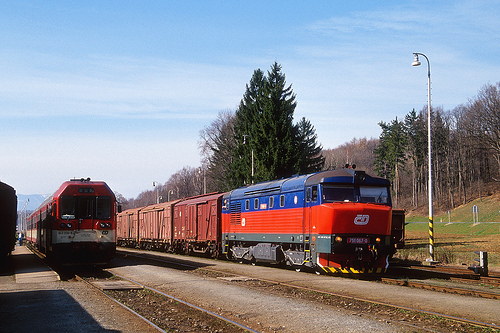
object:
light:
[410, 49, 421, 68]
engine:
[219, 163, 399, 276]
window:
[244, 198, 251, 210]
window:
[253, 197, 260, 210]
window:
[267, 194, 276, 210]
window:
[277, 193, 287, 208]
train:
[116, 161, 395, 279]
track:
[380, 268, 498, 297]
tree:
[209, 57, 321, 192]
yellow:
[339, 267, 349, 273]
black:
[324, 267, 333, 273]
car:
[170, 192, 222, 257]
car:
[137, 199, 178, 252]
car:
[114, 205, 143, 247]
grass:
[402, 204, 498, 238]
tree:
[384, 111, 407, 208]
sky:
[0, 1, 499, 194]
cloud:
[4, 63, 202, 117]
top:
[263, 61, 284, 82]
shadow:
[383, 258, 485, 281]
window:
[320, 184, 360, 203]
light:
[332, 232, 344, 244]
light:
[374, 236, 383, 243]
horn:
[350, 163, 358, 169]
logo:
[351, 211, 373, 227]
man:
[17, 229, 26, 247]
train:
[22, 173, 121, 256]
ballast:
[455, 284, 459, 286]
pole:
[421, 50, 439, 263]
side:
[118, 174, 331, 278]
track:
[71, 271, 259, 333]